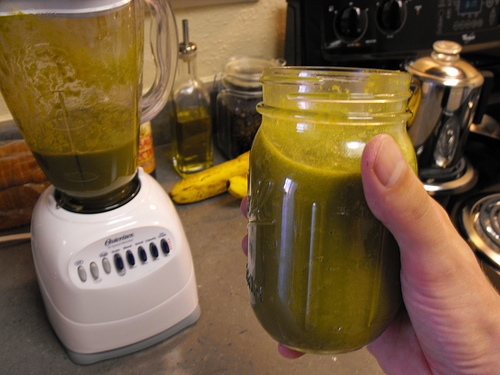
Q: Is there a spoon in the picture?
A: No, there are no spoons.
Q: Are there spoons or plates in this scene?
A: No, there are no spoons or plates.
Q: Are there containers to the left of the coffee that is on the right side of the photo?
A: Yes, there is a container to the left of the coffee.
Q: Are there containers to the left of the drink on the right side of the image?
A: Yes, there is a container to the left of the coffee.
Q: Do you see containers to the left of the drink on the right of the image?
A: Yes, there is a container to the left of the coffee.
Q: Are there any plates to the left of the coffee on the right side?
A: No, there is a container to the left of the coffee.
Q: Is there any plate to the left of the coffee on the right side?
A: No, there is a container to the left of the coffee.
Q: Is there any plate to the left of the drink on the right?
A: No, there is a container to the left of the coffee.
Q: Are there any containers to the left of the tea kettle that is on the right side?
A: Yes, there is a container to the left of the tea kettle.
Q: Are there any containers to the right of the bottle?
A: Yes, there is a container to the right of the bottle.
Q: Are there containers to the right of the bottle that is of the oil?
A: Yes, there is a container to the right of the bottle.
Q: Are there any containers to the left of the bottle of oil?
A: No, the container is to the right of the bottle.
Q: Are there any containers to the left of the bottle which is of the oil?
A: No, the container is to the right of the bottle.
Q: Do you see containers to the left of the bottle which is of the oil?
A: No, the container is to the right of the bottle.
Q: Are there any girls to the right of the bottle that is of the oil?
A: No, there is a container to the right of the bottle.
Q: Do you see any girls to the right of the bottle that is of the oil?
A: No, there is a container to the right of the bottle.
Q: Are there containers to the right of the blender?
A: Yes, there is a container to the right of the blender.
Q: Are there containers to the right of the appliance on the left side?
A: Yes, there is a container to the right of the blender.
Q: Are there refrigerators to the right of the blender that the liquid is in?
A: No, there is a container to the right of the blender.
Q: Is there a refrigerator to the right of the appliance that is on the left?
A: No, there is a container to the right of the blender.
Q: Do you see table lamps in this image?
A: No, there are no table lamps.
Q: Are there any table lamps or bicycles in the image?
A: No, there are no table lamps or bicycles.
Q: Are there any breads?
A: Yes, there is a bread.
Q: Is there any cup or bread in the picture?
A: Yes, there is a bread.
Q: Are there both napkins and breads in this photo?
A: No, there is a bread but no napkins.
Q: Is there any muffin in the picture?
A: No, there are no muffins.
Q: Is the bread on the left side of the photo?
A: Yes, the bread is on the left of the image.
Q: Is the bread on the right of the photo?
A: No, the bread is on the left of the image.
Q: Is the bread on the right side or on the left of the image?
A: The bread is on the left of the image.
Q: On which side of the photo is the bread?
A: The bread is on the left of the image.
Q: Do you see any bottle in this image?
A: Yes, there is a bottle.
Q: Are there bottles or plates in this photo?
A: Yes, there is a bottle.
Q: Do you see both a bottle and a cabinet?
A: No, there is a bottle but no cabinets.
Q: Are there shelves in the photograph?
A: No, there are no shelves.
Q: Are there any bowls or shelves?
A: No, there are no shelves or bowls.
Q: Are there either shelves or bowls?
A: No, there are no shelves or bowls.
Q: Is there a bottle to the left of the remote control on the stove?
A: Yes, there is a bottle to the left of the remote.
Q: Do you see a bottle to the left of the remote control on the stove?
A: Yes, there is a bottle to the left of the remote.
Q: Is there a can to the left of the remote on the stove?
A: No, there is a bottle to the left of the remote control.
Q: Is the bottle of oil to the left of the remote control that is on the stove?
A: Yes, the bottle is to the left of the remote control.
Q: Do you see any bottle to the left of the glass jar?
A: Yes, there is a bottle to the left of the jar.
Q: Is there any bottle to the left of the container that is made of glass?
A: Yes, there is a bottle to the left of the jar.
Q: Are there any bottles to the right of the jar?
A: No, the bottle is to the left of the jar.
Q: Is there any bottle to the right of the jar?
A: No, the bottle is to the left of the jar.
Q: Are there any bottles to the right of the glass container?
A: No, the bottle is to the left of the jar.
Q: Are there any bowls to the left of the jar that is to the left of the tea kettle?
A: No, there is a bottle to the left of the jar.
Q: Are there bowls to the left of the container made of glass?
A: No, there is a bottle to the left of the jar.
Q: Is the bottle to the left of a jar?
A: Yes, the bottle is to the left of a jar.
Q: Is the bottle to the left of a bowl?
A: No, the bottle is to the left of a jar.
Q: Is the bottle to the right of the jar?
A: No, the bottle is to the left of the jar.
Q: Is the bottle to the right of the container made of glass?
A: No, the bottle is to the left of the jar.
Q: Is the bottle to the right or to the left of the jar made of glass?
A: The bottle is to the left of the jar.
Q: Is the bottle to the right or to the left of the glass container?
A: The bottle is to the left of the jar.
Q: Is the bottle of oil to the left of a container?
A: Yes, the bottle is to the left of a container.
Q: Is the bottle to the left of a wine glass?
A: No, the bottle is to the left of a container.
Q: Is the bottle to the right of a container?
A: No, the bottle is to the left of a container.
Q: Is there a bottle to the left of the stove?
A: Yes, there is a bottle to the left of the stove.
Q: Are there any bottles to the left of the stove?
A: Yes, there is a bottle to the left of the stove.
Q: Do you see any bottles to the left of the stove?
A: Yes, there is a bottle to the left of the stove.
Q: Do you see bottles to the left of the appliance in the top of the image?
A: Yes, there is a bottle to the left of the stove.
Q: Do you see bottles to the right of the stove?
A: No, the bottle is to the left of the stove.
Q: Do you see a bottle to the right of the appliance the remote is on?
A: No, the bottle is to the left of the stove.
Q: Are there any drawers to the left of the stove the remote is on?
A: No, there is a bottle to the left of the stove.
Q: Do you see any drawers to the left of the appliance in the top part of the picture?
A: No, there is a bottle to the left of the stove.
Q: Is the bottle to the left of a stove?
A: Yes, the bottle is to the left of a stove.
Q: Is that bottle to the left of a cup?
A: No, the bottle is to the left of a stove.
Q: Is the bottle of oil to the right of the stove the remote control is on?
A: No, the bottle is to the left of the stove.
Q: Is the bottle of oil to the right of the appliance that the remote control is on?
A: No, the bottle is to the left of the stove.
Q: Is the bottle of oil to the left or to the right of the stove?
A: The bottle is to the left of the stove.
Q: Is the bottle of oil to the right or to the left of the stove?
A: The bottle is to the left of the stove.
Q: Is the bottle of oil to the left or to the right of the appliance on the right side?
A: The bottle is to the left of the stove.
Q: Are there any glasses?
A: No, there are no glasses.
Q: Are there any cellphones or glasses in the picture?
A: No, there are no glasses or cellphones.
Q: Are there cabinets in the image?
A: No, there are no cabinets.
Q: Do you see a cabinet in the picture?
A: No, there are no cabinets.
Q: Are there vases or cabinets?
A: No, there are no cabinets or vases.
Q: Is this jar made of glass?
A: Yes, the jar is made of glass.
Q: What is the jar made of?
A: The jar is made of glass.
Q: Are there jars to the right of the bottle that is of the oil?
A: Yes, there is a jar to the right of the bottle.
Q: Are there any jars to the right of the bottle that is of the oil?
A: Yes, there is a jar to the right of the bottle.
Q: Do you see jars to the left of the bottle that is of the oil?
A: No, the jar is to the right of the bottle.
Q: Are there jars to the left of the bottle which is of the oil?
A: No, the jar is to the right of the bottle.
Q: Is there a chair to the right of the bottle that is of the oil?
A: No, there is a jar to the right of the bottle.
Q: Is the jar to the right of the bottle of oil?
A: Yes, the jar is to the right of the bottle.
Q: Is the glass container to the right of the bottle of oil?
A: Yes, the jar is to the right of the bottle.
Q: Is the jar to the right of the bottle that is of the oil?
A: Yes, the jar is to the right of the bottle.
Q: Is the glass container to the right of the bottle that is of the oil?
A: Yes, the jar is to the right of the bottle.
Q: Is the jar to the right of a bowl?
A: No, the jar is to the right of the bottle.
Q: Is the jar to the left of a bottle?
A: No, the jar is to the right of a bottle.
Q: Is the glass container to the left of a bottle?
A: No, the jar is to the right of a bottle.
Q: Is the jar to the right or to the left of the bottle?
A: The jar is to the right of the bottle.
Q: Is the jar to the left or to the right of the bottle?
A: The jar is to the right of the bottle.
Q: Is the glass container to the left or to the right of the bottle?
A: The jar is to the right of the bottle.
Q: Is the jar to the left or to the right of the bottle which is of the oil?
A: The jar is to the right of the bottle.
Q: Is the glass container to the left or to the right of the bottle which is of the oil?
A: The jar is to the right of the bottle.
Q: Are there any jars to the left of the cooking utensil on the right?
A: Yes, there is a jar to the left of the tea kettle.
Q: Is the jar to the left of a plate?
A: No, the jar is to the left of the tea kettle.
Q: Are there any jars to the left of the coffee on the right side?
A: Yes, there is a jar to the left of the coffee.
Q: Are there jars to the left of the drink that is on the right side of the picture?
A: Yes, there is a jar to the left of the coffee.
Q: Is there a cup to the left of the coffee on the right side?
A: No, there is a jar to the left of the coffee.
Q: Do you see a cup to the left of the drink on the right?
A: No, there is a jar to the left of the coffee.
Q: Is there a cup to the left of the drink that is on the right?
A: No, there is a jar to the left of the coffee.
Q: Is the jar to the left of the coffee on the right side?
A: Yes, the jar is to the left of the coffee.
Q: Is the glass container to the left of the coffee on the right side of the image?
A: Yes, the jar is to the left of the coffee.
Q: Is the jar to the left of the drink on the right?
A: Yes, the jar is to the left of the coffee.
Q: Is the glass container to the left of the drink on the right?
A: Yes, the jar is to the left of the coffee.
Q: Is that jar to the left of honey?
A: No, the jar is to the left of the coffee.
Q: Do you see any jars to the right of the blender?
A: Yes, there is a jar to the right of the blender.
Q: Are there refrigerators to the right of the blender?
A: No, there is a jar to the right of the blender.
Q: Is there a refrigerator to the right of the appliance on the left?
A: No, there is a jar to the right of the blender.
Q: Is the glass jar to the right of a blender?
A: Yes, the jar is to the right of a blender.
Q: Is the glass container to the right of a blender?
A: Yes, the jar is to the right of a blender.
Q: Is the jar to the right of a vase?
A: No, the jar is to the right of a blender.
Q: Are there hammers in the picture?
A: No, there are no hammers.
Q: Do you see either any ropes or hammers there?
A: No, there are no hammers or ropes.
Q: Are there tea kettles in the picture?
A: Yes, there is a tea kettle.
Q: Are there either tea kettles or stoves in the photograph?
A: Yes, there is a tea kettle.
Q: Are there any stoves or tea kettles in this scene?
A: Yes, there is a tea kettle.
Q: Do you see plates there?
A: No, there are no plates.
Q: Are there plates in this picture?
A: No, there are no plates.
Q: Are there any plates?
A: No, there are no plates.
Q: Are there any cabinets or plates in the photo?
A: No, there are no plates or cabinets.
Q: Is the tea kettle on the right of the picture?
A: Yes, the tea kettle is on the right of the image.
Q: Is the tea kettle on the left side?
A: No, the tea kettle is on the right of the image.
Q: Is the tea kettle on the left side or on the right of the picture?
A: The tea kettle is on the right of the image.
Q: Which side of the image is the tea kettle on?
A: The tea kettle is on the right of the image.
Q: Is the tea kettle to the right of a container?
A: Yes, the tea kettle is to the right of a container.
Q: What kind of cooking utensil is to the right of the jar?
A: The cooking utensil is a tea kettle.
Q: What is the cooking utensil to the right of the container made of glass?
A: The cooking utensil is a tea kettle.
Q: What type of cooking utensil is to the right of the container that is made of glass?
A: The cooking utensil is a tea kettle.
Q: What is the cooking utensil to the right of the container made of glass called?
A: The cooking utensil is a tea kettle.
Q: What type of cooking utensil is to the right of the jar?
A: The cooking utensil is a tea kettle.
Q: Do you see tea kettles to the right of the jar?
A: Yes, there is a tea kettle to the right of the jar.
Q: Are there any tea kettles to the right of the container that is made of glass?
A: Yes, there is a tea kettle to the right of the jar.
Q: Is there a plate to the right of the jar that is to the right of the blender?
A: No, there is a tea kettle to the right of the jar.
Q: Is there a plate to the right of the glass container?
A: No, there is a tea kettle to the right of the jar.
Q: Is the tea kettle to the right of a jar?
A: Yes, the tea kettle is to the right of a jar.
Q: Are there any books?
A: No, there are no books.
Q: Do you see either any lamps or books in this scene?
A: No, there are no books or lamps.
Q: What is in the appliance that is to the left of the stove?
A: The liquid is in the blender.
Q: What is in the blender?
A: The liquid is in the blender.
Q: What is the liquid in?
A: The liquid is in the blender.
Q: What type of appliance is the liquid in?
A: The liquid is in the blender.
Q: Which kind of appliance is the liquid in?
A: The liquid is in the blender.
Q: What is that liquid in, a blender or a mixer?
A: The liquid is in a blender.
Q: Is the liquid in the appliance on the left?
A: Yes, the liquid is in the blender.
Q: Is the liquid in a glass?
A: No, the liquid is in the blender.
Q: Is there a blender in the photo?
A: Yes, there is a blender.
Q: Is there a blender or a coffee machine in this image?
A: Yes, there is a blender.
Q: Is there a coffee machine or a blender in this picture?
A: Yes, there is a blender.